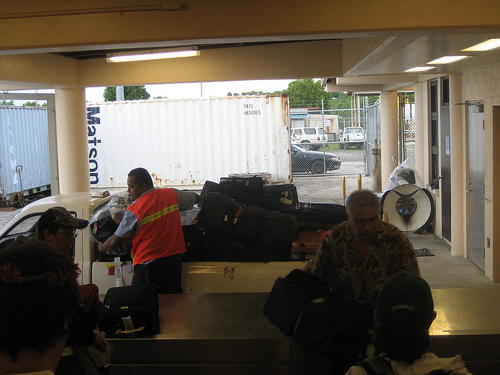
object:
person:
[343, 272, 473, 375]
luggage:
[220, 175, 265, 193]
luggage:
[263, 184, 298, 203]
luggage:
[98, 285, 159, 338]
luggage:
[263, 268, 337, 343]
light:
[106, 51, 201, 63]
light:
[403, 66, 437, 72]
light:
[426, 56, 470, 64]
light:
[461, 37, 500, 51]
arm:
[99, 210, 137, 254]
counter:
[91, 288, 500, 375]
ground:
[301, 179, 336, 196]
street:
[325, 149, 365, 163]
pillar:
[449, 74, 465, 258]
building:
[320, 31, 500, 283]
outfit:
[124, 188, 187, 266]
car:
[338, 127, 367, 149]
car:
[290, 127, 328, 151]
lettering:
[84, 107, 101, 184]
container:
[87, 94, 294, 191]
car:
[291, 144, 341, 174]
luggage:
[88, 195, 139, 256]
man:
[302, 188, 420, 342]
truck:
[87, 94, 292, 192]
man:
[98, 168, 201, 295]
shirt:
[303, 219, 420, 310]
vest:
[125, 188, 186, 266]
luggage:
[198, 191, 299, 247]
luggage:
[292, 231, 327, 253]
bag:
[198, 191, 298, 252]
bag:
[88, 195, 137, 255]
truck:
[0, 190, 312, 294]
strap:
[219, 202, 243, 234]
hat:
[38, 206, 89, 229]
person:
[5, 206, 113, 375]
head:
[127, 168, 153, 201]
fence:
[290, 98, 382, 177]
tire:
[310, 159, 327, 173]